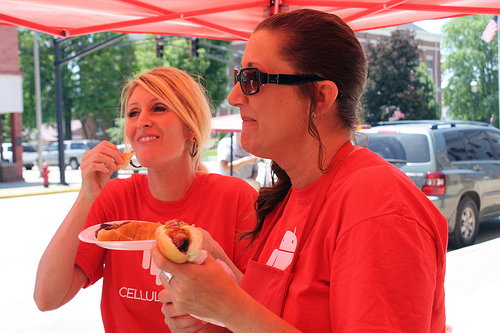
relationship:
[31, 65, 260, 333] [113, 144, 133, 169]
woman holding chip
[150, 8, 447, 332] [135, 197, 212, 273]
woman holding hotdog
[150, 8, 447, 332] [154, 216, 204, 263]
woman eating hotdog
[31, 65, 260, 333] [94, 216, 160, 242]
woman eating hotdog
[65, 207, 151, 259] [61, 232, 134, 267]
hot dog in plate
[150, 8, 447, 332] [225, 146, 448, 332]
woman wearing shirt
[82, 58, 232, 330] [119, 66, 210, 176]
woman with hair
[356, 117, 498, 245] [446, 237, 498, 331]
suv parked along curb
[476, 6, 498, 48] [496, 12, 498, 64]
american flag on flag pole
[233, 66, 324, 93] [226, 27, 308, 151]
sunglasses on face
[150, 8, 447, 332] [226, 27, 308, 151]
woman has face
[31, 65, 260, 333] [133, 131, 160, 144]
woman smiling showing teeth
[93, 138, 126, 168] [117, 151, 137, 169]
hand holding onto chip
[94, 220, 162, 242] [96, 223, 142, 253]
hot dog on plate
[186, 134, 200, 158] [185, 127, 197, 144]
hooped earing on ear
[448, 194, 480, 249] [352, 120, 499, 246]
back wheel of car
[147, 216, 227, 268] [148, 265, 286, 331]
hot dog on top of hand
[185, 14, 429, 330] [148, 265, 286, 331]
woman has hand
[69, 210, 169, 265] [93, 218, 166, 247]
plate containing hot dog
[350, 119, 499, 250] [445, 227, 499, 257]
suv on side of street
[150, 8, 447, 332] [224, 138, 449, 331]
woman wearing shirt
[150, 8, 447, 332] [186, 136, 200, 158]
woman wears hooped earing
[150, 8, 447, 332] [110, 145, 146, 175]
woman wears round earring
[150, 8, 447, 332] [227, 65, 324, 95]
woman wears sunglasses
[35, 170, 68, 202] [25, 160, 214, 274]
fire hydrant on street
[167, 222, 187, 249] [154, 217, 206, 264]
wiener on hot dog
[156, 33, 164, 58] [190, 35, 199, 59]
traffic light light street light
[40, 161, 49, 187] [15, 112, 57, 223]
fire hydrant hydrant in distance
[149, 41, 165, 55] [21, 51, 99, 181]
traffic light in distance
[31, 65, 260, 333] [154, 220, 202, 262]
woman hand holding a hotdog